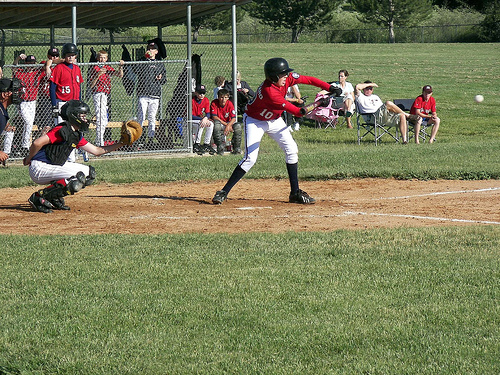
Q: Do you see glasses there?
A: No, there are no glasses.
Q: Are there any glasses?
A: No, there are no glasses.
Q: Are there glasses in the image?
A: No, there are no glasses.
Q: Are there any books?
A: No, there are no books.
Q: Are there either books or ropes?
A: No, there are no books or ropes.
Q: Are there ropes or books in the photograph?
A: No, there are no books or ropes.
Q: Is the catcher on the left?
A: Yes, the catcher is on the left of the image.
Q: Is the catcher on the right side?
A: No, the catcher is on the left of the image.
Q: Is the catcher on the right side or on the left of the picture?
A: The catcher is on the left of the image.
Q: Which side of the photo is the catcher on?
A: The catcher is on the left of the image.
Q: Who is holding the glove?
A: The catcher is holding the glove.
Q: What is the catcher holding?
A: The catcher is holding the glove.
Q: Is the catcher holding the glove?
A: Yes, the catcher is holding the glove.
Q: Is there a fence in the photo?
A: Yes, there is a fence.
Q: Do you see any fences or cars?
A: Yes, there is a fence.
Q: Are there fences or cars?
A: Yes, there is a fence.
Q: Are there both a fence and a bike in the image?
A: No, there is a fence but no bikes.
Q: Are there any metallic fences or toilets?
A: Yes, there is a metal fence.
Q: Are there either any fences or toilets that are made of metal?
A: Yes, the fence is made of metal.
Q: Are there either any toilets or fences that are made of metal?
A: Yes, the fence is made of metal.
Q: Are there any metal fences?
A: Yes, there is a metal fence.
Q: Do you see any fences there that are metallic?
A: Yes, there is a fence that is metallic.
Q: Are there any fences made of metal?
A: Yes, there is a fence that is made of metal.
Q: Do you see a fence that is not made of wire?
A: Yes, there is a fence that is made of metal.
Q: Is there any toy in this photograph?
A: No, there are no toys.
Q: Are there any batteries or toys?
A: No, there are no toys or batteries.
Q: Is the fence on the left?
A: Yes, the fence is on the left of the image.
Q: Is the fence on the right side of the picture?
A: No, the fence is on the left of the image.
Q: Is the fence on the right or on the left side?
A: The fence is on the left of the image.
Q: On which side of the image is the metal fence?
A: The fence is on the left of the image.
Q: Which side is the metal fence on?
A: The fence is on the left of the image.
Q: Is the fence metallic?
A: Yes, the fence is metallic.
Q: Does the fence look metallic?
A: Yes, the fence is metallic.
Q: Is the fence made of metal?
A: Yes, the fence is made of metal.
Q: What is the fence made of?
A: The fence is made of metal.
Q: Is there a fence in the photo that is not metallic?
A: No, there is a fence but it is metallic.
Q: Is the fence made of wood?
A: No, the fence is made of metal.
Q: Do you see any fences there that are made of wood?
A: No, there is a fence but it is made of metal.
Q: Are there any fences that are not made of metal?
A: No, there is a fence but it is made of metal.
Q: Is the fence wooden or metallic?
A: The fence is metallic.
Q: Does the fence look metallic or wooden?
A: The fence is metallic.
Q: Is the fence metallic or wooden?
A: The fence is metallic.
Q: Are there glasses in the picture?
A: No, there are no glasses.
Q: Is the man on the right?
A: Yes, the man is on the right of the image.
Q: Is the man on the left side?
A: No, the man is on the right of the image.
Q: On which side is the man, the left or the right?
A: The man is on the right of the image.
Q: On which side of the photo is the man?
A: The man is on the right of the image.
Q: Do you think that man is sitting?
A: Yes, the man is sitting.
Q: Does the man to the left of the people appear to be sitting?
A: Yes, the man is sitting.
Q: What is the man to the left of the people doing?
A: The man is sitting.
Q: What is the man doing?
A: The man is sitting.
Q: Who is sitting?
A: The man is sitting.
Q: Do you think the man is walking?
A: No, the man is sitting.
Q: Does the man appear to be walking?
A: No, the man is sitting.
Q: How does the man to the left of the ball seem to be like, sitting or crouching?
A: The man is sitting.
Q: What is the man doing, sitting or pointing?
A: The man is sitting.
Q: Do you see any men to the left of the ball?
A: Yes, there is a man to the left of the ball.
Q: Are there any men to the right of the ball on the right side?
A: No, the man is to the left of the ball.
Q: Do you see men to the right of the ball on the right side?
A: No, the man is to the left of the ball.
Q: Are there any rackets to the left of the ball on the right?
A: No, there is a man to the left of the ball.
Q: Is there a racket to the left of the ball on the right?
A: No, there is a man to the left of the ball.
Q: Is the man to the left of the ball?
A: Yes, the man is to the left of the ball.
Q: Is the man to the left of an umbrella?
A: No, the man is to the left of the ball.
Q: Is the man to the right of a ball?
A: No, the man is to the left of a ball.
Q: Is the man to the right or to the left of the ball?
A: The man is to the left of the ball.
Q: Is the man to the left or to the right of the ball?
A: The man is to the left of the ball.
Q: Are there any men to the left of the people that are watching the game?
A: Yes, there is a man to the left of the people.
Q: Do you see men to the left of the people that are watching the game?
A: Yes, there is a man to the left of the people.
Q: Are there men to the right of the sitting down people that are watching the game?
A: No, the man is to the left of the people.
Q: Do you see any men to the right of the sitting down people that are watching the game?
A: No, the man is to the left of the people.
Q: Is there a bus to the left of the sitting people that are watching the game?
A: No, there is a man to the left of the people.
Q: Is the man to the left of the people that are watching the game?
A: Yes, the man is to the left of the people.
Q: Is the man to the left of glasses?
A: No, the man is to the left of the people.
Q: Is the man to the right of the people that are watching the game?
A: No, the man is to the left of the people.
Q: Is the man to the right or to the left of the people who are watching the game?
A: The man is to the left of the people.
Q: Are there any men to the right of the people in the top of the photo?
A: Yes, there is a man to the right of the people.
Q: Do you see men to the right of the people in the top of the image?
A: Yes, there is a man to the right of the people.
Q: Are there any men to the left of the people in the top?
A: No, the man is to the right of the people.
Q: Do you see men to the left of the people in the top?
A: No, the man is to the right of the people.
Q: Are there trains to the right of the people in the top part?
A: No, there is a man to the right of the people.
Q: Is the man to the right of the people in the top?
A: Yes, the man is to the right of the people.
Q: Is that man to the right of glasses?
A: No, the man is to the right of the people.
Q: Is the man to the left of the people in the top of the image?
A: No, the man is to the right of the people.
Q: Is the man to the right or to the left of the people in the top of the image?
A: The man is to the right of the people.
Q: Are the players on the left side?
A: Yes, the players are on the left of the image.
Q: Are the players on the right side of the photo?
A: No, the players are on the left of the image.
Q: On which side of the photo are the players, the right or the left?
A: The players are on the left of the image.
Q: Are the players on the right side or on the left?
A: The players are on the left of the image.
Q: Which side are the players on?
A: The players are on the left of the image.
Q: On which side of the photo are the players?
A: The players are on the left of the image.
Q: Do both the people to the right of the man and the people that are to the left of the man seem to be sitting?
A: Yes, both the people and the people are sitting.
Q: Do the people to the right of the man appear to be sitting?
A: Yes, the people are sitting.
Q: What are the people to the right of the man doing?
A: The people are sitting.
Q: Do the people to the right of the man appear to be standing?
A: No, the people are sitting.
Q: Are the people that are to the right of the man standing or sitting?
A: The people are sitting.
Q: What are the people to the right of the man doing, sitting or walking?
A: The people are sitting.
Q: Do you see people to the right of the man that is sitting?
A: Yes, there are people to the right of the man.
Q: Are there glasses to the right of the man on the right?
A: No, there are people to the right of the man.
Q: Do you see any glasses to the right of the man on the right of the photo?
A: No, there are people to the right of the man.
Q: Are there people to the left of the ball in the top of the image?
A: Yes, there are people to the left of the ball.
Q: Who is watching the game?
A: The people are watching the game.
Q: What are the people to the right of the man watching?
A: The people are watching the game.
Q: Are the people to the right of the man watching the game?
A: Yes, the people are watching the game.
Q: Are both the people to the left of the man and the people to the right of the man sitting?
A: Yes, both the people and the people are sitting.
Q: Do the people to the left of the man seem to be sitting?
A: Yes, the people are sitting.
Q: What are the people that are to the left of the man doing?
A: The people are sitting.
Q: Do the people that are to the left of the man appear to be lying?
A: No, the people are sitting.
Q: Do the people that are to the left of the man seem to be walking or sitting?
A: The people are sitting.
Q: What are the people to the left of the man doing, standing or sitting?
A: The people are sitting.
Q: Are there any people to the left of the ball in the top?
A: Yes, there are people to the left of the ball.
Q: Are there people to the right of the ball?
A: No, the people are to the left of the ball.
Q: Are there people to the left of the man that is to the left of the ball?
A: Yes, there are people to the left of the man.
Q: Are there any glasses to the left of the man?
A: No, there are people to the left of the man.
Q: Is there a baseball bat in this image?
A: Yes, there is a baseball bat.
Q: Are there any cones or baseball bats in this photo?
A: Yes, there is a baseball bat.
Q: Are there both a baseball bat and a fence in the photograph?
A: Yes, there are both a baseball bat and a fence.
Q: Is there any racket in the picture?
A: No, there are no rackets.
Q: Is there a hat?
A: Yes, there is a hat.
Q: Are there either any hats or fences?
A: Yes, there is a hat.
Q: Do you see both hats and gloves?
A: Yes, there are both a hat and gloves.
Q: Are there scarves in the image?
A: No, there are no scarves.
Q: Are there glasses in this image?
A: No, there are no glasses.